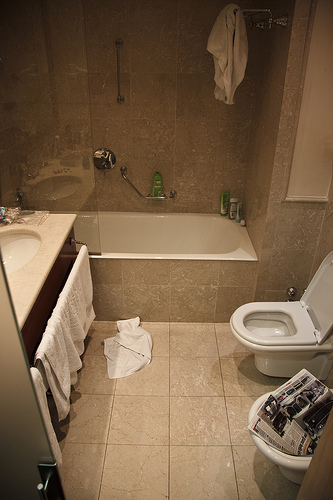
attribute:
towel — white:
[96, 314, 161, 383]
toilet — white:
[232, 235, 331, 385]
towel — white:
[32, 241, 97, 466]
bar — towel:
[47, 232, 88, 384]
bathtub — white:
[35, 207, 260, 262]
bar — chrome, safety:
[107, 33, 127, 105]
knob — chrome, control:
[90, 145, 123, 175]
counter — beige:
[1, 208, 78, 342]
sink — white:
[5, 223, 41, 277]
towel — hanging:
[203, 1, 255, 111]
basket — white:
[246, 385, 331, 485]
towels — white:
[9, 245, 96, 467]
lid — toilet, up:
[303, 243, 332, 340]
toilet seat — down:
[228, 293, 317, 346]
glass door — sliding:
[1, 1, 102, 255]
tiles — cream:
[95, 393, 238, 497]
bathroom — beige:
[1, 1, 331, 496]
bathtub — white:
[74, 212, 255, 322]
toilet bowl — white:
[234, 303, 326, 369]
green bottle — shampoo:
[147, 168, 165, 198]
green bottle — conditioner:
[219, 185, 232, 215]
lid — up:
[300, 251, 332, 335]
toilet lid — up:
[301, 251, 332, 343]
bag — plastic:
[0, 206, 50, 226]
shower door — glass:
[0, 0, 102, 254]